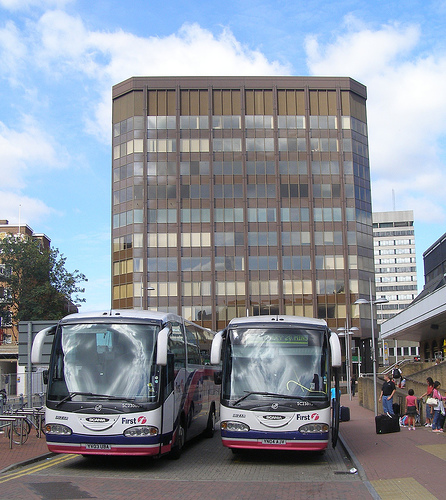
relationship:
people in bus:
[370, 350, 444, 453] [30, 309, 222, 461]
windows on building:
[111, 114, 381, 336] [104, 72, 395, 407]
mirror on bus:
[30, 326, 56, 364] [37, 299, 193, 477]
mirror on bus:
[154, 325, 175, 363] [29, 297, 227, 452]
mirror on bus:
[208, 330, 223, 365] [208, 310, 346, 457]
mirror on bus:
[27, 326, 51, 362] [208, 310, 346, 457]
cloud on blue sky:
[0, 0, 444, 171] [82, 1, 327, 34]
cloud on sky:
[294, 17, 444, 171] [0, 1, 446, 311]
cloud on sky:
[0, 0, 444, 171] [0, 1, 446, 311]